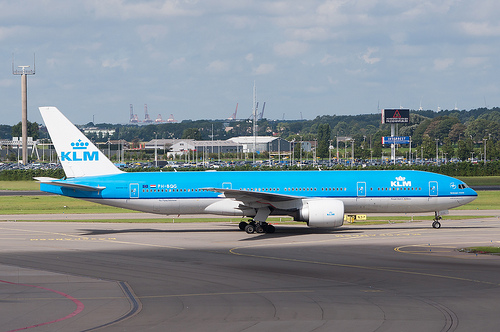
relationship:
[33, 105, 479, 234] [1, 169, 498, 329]
airplane on ground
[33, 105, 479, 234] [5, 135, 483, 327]
airplane at airport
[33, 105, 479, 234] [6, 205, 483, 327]
airplane on runway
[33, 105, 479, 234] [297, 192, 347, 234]
airplane has engine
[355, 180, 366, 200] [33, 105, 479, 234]
door of airplane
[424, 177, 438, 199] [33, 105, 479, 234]
door of airplane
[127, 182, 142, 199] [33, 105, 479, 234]
door of airplane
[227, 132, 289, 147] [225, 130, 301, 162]
roof of building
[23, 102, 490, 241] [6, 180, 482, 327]
airplane on runway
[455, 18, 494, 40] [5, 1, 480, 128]
clouds in sky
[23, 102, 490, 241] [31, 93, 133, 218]
airplane has tail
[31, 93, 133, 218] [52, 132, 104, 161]
tail with logo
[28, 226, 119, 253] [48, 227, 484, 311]
lines on runway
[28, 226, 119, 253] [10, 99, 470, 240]
lines guide planes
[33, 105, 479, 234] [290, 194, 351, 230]
airplane has engine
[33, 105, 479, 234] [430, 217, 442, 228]
airplane has landing gear